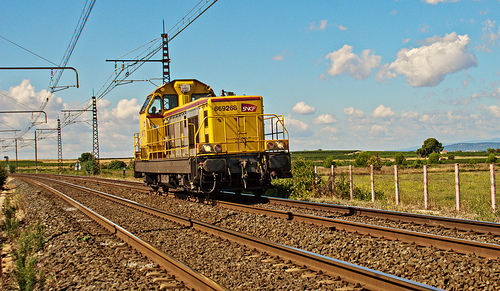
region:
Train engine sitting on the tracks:
[130, 79, 297, 192]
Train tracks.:
[27, 168, 495, 289]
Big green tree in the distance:
[419, 130, 447, 152]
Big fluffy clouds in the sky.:
[323, 46, 494, 136]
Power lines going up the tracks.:
[18, 5, 209, 132]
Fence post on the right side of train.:
[306, 163, 498, 215]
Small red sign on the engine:
[239, 99, 257, 115]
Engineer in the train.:
[147, 98, 160, 115]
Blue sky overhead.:
[2, 5, 498, 40]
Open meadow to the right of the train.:
[348, 166, 498, 201]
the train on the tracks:
[134, 78, 289, 208]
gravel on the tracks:
[282, 215, 373, 262]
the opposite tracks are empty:
[36, 172, 452, 289]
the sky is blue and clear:
[195, 11, 273, 68]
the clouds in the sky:
[355, 21, 459, 95]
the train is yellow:
[125, 79, 295, 194]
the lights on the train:
[193, 136, 292, 151]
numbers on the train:
[211, 99, 243, 114]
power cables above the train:
[97, 0, 222, 102]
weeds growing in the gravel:
[5, 211, 50, 277]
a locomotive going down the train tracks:
[106, 20, 499, 278]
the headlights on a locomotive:
[201, 140, 221, 152]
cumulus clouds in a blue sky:
[291, 28, 499, 131]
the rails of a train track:
[22, 199, 317, 289]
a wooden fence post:
[485, 158, 499, 217]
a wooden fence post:
[448, 155, 469, 207]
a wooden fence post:
[420, 159, 432, 211]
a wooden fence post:
[389, 160, 405, 205]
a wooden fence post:
[367, 160, 377, 204]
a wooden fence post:
[346, 160, 357, 199]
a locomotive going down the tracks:
[129, 80, 497, 251]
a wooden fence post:
[324, 158, 335, 195]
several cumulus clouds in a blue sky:
[300, 20, 497, 141]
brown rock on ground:
[68, 260, 113, 283]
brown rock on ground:
[60, 232, 100, 260]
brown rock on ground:
[37, 209, 63, 227]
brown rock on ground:
[34, 196, 59, 213]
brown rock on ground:
[71, 191, 100, 204]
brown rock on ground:
[114, 207, 141, 234]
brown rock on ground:
[166, 221, 203, 251]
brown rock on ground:
[201, 247, 242, 273]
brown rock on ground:
[260, 272, 290, 289]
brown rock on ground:
[299, 232, 357, 248]